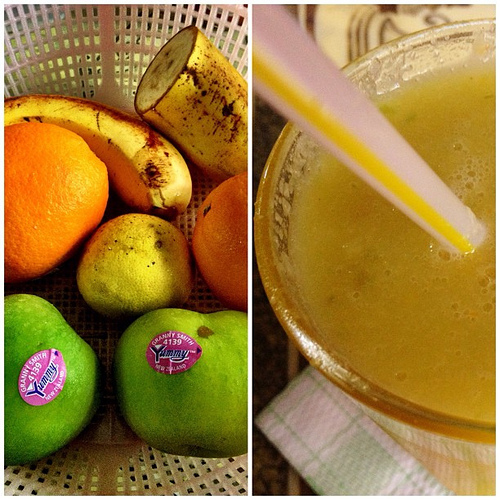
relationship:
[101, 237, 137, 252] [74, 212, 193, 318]
bruises on lemon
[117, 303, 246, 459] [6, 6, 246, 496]
apple in a basket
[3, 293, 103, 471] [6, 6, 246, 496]
apple in a basket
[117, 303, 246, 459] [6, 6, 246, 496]
apple are in basket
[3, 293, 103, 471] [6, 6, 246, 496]
apple are in basket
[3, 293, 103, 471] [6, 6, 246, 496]
apple are in a basket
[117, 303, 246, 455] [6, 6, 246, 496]
apple are in a basket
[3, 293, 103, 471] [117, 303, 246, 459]
apple in a apple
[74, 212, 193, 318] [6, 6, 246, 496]
lemon in a basket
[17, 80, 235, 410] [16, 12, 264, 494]
fruit in a basket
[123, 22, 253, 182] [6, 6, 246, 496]
banana in a basket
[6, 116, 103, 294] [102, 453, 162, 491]
orange in basket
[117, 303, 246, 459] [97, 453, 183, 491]
apple in basket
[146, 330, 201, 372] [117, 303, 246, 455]
label on apple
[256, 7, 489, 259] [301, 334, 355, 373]
straw in a glass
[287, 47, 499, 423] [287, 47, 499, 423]
bubble in bubble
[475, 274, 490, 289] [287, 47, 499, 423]
bubble in bubble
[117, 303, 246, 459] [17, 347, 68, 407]
apple has a label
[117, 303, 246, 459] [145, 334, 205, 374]
apple has a sticker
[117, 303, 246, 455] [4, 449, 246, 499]
apple in a white basket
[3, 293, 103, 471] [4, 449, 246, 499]
apple in a white basket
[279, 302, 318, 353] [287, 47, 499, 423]
glass has orange bubble